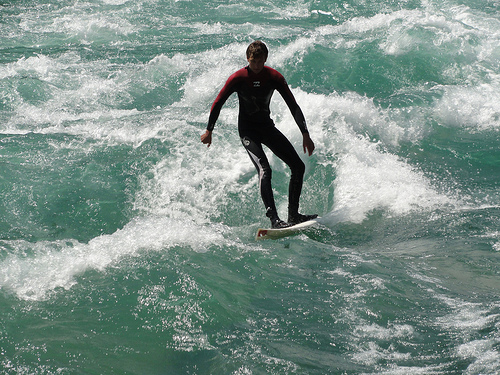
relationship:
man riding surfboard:
[202, 33, 325, 222] [256, 215, 335, 238]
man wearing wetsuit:
[202, 33, 325, 222] [245, 70, 299, 213]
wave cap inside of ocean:
[347, 166, 437, 213] [18, 237, 481, 357]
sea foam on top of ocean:
[67, 235, 143, 267] [18, 237, 481, 357]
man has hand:
[202, 33, 325, 222] [202, 130, 213, 145]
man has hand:
[202, 33, 325, 222] [302, 136, 319, 156]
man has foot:
[202, 33, 325, 222] [271, 217, 289, 229]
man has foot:
[202, 33, 325, 222] [289, 212, 323, 222]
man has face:
[202, 33, 325, 222] [249, 55, 266, 74]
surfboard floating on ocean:
[256, 215, 335, 238] [18, 237, 481, 357]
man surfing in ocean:
[202, 33, 325, 222] [18, 237, 481, 357]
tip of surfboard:
[256, 226, 271, 238] [256, 215, 335, 238]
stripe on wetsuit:
[250, 153, 268, 189] [245, 70, 299, 213]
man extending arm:
[202, 33, 325, 222] [284, 91, 318, 133]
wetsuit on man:
[245, 70, 299, 213] [202, 33, 325, 222]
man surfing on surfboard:
[202, 33, 325, 222] [256, 215, 335, 238]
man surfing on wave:
[202, 33, 325, 222] [307, 27, 462, 78]